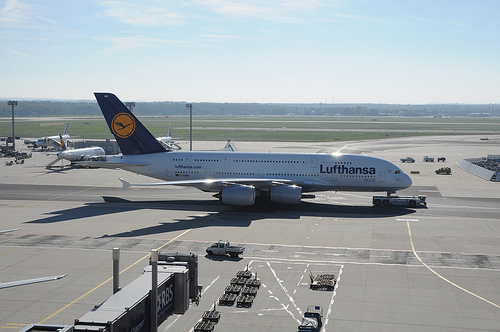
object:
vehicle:
[371, 192, 430, 208]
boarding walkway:
[67, 246, 210, 329]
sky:
[2, 2, 495, 109]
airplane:
[68, 93, 414, 209]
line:
[398, 222, 498, 313]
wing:
[0, 266, 70, 297]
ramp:
[148, 250, 204, 302]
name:
[319, 164, 377, 175]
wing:
[103, 179, 293, 193]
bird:
[115, 121, 134, 130]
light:
[185, 103, 193, 151]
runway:
[229, 107, 457, 152]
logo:
[319, 164, 376, 175]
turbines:
[269, 184, 303, 206]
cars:
[434, 166, 452, 175]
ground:
[320, 231, 417, 291]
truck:
[206, 239, 247, 258]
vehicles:
[399, 155, 417, 162]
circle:
[110, 111, 136, 138]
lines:
[68, 233, 228, 243]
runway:
[57, 147, 371, 280]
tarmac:
[0, 141, 480, 330]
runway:
[3, 112, 483, 123]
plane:
[69, 90, 413, 209]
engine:
[212, 185, 260, 207]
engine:
[270, 185, 303, 206]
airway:
[0, 142, 483, 330]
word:
[318, 161, 378, 176]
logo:
[111, 112, 137, 140]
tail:
[91, 91, 167, 153]